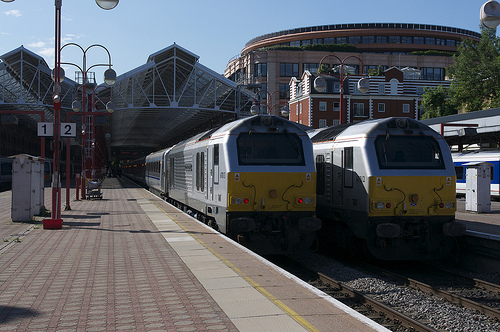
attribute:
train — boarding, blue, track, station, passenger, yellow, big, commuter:
[102, 90, 329, 227]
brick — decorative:
[53, 199, 156, 287]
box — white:
[8, 158, 45, 217]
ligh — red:
[242, 195, 258, 206]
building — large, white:
[229, 11, 483, 119]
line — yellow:
[246, 281, 300, 318]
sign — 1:
[36, 109, 57, 142]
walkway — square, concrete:
[100, 214, 166, 266]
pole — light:
[96, 33, 131, 133]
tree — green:
[420, 48, 483, 99]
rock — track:
[396, 284, 418, 298]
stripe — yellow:
[231, 278, 279, 312]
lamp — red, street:
[78, 54, 119, 124]